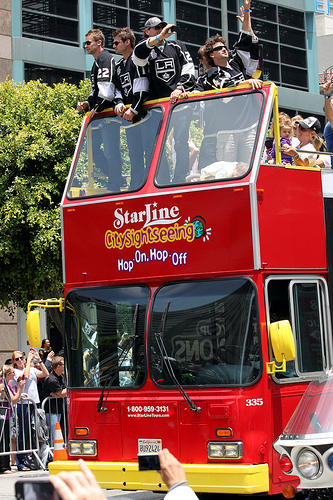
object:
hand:
[111, 26, 136, 54]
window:
[256, 269, 329, 396]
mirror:
[265, 318, 296, 379]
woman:
[282, 116, 320, 168]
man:
[201, 0, 263, 90]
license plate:
[135, 436, 163, 458]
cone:
[52, 421, 67, 463]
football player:
[132, 17, 197, 102]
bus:
[47, 81, 332, 500]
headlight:
[206, 438, 245, 462]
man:
[5, 345, 49, 471]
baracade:
[0, 393, 70, 457]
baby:
[270, 112, 295, 165]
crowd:
[0, 335, 65, 472]